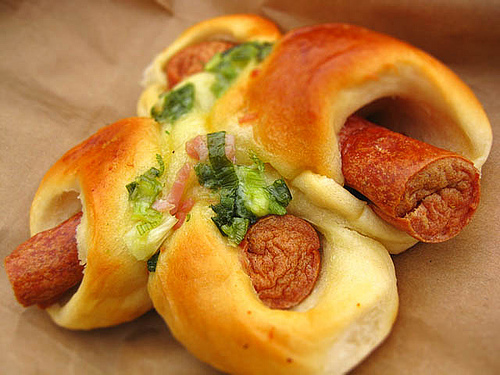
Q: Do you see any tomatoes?
A: Yes, there is a tomato.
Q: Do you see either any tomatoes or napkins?
A: Yes, there is a tomato.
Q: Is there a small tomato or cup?
A: Yes, there is a small tomato.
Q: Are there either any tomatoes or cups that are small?
A: Yes, the tomato is small.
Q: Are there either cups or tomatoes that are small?
A: Yes, the tomato is small.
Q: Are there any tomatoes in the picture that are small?
A: Yes, there is a small tomato.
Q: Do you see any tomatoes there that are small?
A: Yes, there is a tomato that is small.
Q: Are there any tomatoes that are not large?
A: Yes, there is a small tomato.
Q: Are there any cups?
A: No, there are no cups.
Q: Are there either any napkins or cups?
A: No, there are no cups or napkins.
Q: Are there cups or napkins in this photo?
A: No, there are no cups or napkins.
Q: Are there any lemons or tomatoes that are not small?
A: No, there is a tomato but it is small.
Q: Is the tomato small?
A: Yes, the tomato is small.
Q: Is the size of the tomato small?
A: Yes, the tomato is small.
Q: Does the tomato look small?
A: Yes, the tomato is small.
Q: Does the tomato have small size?
A: Yes, the tomato is small.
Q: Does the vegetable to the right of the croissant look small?
A: Yes, the tomato is small.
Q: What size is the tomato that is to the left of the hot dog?
A: The tomato is small.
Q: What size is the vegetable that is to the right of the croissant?
A: The tomato is small.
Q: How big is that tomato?
A: The tomato is small.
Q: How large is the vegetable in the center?
A: The tomato is small.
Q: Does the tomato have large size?
A: No, the tomato is small.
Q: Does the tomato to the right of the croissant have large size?
A: No, the tomato is small.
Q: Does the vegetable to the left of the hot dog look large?
A: No, the tomato is small.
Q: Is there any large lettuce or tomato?
A: No, there is a tomato but it is small.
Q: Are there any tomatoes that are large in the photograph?
A: No, there is a tomato but it is small.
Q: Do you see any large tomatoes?
A: No, there is a tomato but it is small.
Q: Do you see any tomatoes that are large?
A: No, there is a tomato but it is small.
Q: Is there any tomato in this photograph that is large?
A: No, there is a tomato but it is small.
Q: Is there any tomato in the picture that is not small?
A: No, there is a tomato but it is small.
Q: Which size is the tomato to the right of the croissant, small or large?
A: The tomato is small.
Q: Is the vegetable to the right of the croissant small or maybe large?
A: The tomato is small.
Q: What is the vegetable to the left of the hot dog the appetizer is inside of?
A: The vegetable is a tomato.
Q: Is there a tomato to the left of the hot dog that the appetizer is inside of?
A: Yes, there is a tomato to the left of the hot dog.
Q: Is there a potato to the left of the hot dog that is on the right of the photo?
A: No, there is a tomato to the left of the hot dog.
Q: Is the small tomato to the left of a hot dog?
A: Yes, the tomato is to the left of a hot dog.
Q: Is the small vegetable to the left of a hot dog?
A: Yes, the tomato is to the left of a hot dog.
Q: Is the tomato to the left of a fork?
A: No, the tomato is to the left of a hot dog.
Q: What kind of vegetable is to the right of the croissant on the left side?
A: The vegetable is a tomato.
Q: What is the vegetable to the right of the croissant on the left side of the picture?
A: The vegetable is a tomato.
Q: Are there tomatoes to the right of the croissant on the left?
A: Yes, there is a tomato to the right of the croissant.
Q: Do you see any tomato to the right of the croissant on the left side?
A: Yes, there is a tomato to the right of the croissant.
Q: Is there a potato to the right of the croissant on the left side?
A: No, there is a tomato to the right of the croissant.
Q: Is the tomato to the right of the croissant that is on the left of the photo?
A: Yes, the tomato is to the right of the croissant.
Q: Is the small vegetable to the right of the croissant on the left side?
A: Yes, the tomato is to the right of the croissant.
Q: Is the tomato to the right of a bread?
A: No, the tomato is to the right of the croissant.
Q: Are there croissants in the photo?
A: Yes, there is a croissant.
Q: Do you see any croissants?
A: Yes, there is a croissant.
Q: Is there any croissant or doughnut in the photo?
A: Yes, there is a croissant.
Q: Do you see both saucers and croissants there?
A: No, there is a croissant but no saucers.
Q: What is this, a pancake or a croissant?
A: This is a croissant.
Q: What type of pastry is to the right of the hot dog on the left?
A: The pastry is a croissant.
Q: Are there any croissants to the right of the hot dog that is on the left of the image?
A: Yes, there is a croissant to the right of the hot dog.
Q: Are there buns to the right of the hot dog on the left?
A: No, there is a croissant to the right of the hot dog.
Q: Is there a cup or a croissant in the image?
A: Yes, there is a croissant.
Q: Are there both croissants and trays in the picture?
A: No, there is a croissant but no trays.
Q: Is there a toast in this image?
A: No, there are no toasts.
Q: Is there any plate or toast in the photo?
A: No, there are no toasts or plates.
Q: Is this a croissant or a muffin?
A: This is a croissant.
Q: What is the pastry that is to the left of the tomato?
A: The pastry is a croissant.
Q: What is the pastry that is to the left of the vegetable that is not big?
A: The pastry is a croissant.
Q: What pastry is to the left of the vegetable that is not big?
A: The pastry is a croissant.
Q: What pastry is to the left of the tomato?
A: The pastry is a croissant.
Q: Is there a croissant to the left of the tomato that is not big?
A: Yes, there is a croissant to the left of the tomato.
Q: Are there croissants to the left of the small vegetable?
A: Yes, there is a croissant to the left of the tomato.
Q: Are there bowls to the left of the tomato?
A: No, there is a croissant to the left of the tomato.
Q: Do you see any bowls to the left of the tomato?
A: No, there is a croissant to the left of the tomato.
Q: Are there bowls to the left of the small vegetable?
A: No, there is a croissant to the left of the tomato.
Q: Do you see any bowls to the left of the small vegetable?
A: No, there is a croissant to the left of the tomato.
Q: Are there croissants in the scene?
A: Yes, there is a croissant.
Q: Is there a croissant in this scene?
A: Yes, there is a croissant.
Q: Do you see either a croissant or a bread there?
A: Yes, there is a croissant.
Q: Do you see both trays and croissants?
A: No, there is a croissant but no trays.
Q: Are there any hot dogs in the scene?
A: Yes, there is a hot dog.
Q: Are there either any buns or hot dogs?
A: Yes, there is a hot dog.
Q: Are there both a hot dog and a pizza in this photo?
A: No, there is a hot dog but no pizzas.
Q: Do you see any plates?
A: No, there are no plates.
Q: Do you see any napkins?
A: No, there are no napkins.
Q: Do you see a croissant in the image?
A: Yes, there is a croissant.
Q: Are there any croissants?
A: Yes, there is a croissant.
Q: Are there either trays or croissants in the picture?
A: Yes, there is a croissant.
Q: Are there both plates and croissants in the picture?
A: No, there is a croissant but no plates.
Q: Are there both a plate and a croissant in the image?
A: No, there is a croissant but no plates.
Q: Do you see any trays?
A: No, there are no trays.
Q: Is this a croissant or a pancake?
A: This is a croissant.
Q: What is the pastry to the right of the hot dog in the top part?
A: The pastry is a croissant.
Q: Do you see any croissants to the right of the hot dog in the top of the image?
A: Yes, there is a croissant to the right of the hot dog.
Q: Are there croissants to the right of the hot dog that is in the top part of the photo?
A: Yes, there is a croissant to the right of the hot dog.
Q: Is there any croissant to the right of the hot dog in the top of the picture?
A: Yes, there is a croissant to the right of the hot dog.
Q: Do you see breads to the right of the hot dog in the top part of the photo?
A: No, there is a croissant to the right of the hot dog.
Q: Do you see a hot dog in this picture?
A: Yes, there is a hot dog.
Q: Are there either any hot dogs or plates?
A: Yes, there is a hot dog.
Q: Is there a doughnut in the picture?
A: No, there are no donuts.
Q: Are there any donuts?
A: No, there are no donuts.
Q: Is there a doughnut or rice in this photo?
A: No, there are no donuts or rice.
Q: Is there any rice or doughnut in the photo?
A: No, there are no donuts or rice.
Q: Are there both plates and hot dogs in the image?
A: No, there is a hot dog but no plates.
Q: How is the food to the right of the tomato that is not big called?
A: The food is a hot dog.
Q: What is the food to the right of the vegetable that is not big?
A: The food is a hot dog.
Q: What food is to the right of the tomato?
A: The food is a hot dog.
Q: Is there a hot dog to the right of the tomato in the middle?
A: Yes, there is a hot dog to the right of the tomato.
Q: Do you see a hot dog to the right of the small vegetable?
A: Yes, there is a hot dog to the right of the tomato.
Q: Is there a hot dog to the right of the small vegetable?
A: Yes, there is a hot dog to the right of the tomato.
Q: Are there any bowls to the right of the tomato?
A: No, there is a hot dog to the right of the tomato.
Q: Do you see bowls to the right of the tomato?
A: No, there is a hot dog to the right of the tomato.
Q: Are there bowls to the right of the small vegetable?
A: No, there is a hot dog to the right of the tomato.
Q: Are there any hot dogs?
A: Yes, there is a hot dog.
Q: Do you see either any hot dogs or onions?
A: Yes, there is a hot dog.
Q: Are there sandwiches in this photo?
A: No, there are no sandwiches.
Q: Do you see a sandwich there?
A: No, there are no sandwiches.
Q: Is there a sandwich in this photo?
A: No, there are no sandwiches.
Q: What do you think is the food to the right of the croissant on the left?
A: The food is a hot dog.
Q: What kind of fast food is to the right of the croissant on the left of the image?
A: The food is a hot dog.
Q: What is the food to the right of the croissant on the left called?
A: The food is a hot dog.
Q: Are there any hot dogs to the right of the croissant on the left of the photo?
A: Yes, there is a hot dog to the right of the croissant.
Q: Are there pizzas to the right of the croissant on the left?
A: No, there is a hot dog to the right of the croissant.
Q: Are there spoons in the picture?
A: No, there are no spoons.